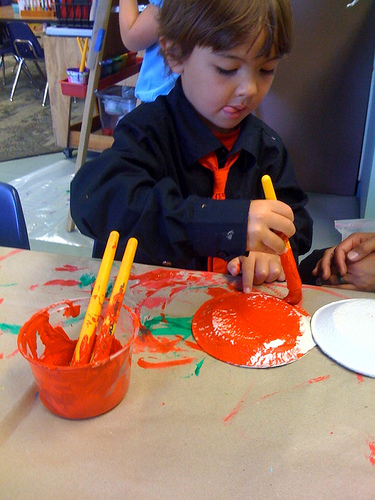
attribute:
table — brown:
[0, 245, 374, 498]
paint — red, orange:
[18, 297, 139, 420]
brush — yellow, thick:
[89, 234, 138, 363]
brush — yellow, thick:
[70, 228, 119, 365]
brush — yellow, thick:
[258, 173, 302, 299]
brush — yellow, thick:
[80, 35, 90, 69]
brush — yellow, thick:
[73, 36, 89, 71]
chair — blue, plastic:
[0, 179, 30, 248]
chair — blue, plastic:
[5, 18, 50, 107]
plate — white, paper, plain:
[309, 296, 374, 381]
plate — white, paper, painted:
[191, 293, 316, 369]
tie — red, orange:
[198, 150, 241, 274]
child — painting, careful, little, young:
[69, 0, 314, 297]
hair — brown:
[159, 0, 293, 81]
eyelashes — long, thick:
[214, 64, 238, 75]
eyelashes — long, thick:
[260, 68, 276, 76]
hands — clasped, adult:
[312, 231, 374, 294]